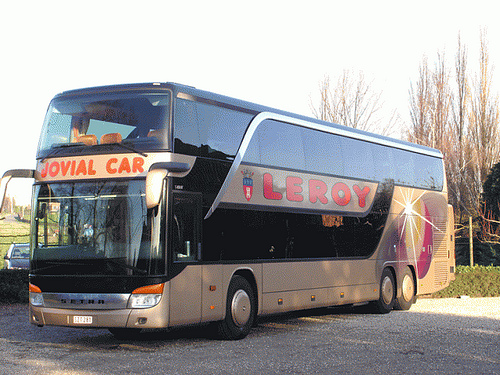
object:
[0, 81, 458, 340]
bus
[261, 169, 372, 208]
word leroy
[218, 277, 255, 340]
tire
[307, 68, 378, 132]
tree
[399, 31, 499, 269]
tree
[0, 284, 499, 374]
ground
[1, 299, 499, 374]
shadow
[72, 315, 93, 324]
license plate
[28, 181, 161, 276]
window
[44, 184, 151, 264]
reflection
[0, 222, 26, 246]
grass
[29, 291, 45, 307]
headlight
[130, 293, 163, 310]
headlight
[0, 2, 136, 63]
sky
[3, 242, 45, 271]
car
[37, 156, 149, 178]
jovial car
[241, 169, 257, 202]
design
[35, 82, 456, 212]
top cabin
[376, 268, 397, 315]
tire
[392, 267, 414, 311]
tire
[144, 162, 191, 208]
side mirror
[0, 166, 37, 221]
side mirror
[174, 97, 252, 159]
side window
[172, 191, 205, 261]
side window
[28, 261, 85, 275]
windshield washer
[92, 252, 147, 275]
windshield wiper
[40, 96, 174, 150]
top window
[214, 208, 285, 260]
passenger window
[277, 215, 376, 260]
passenger window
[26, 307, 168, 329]
bumper